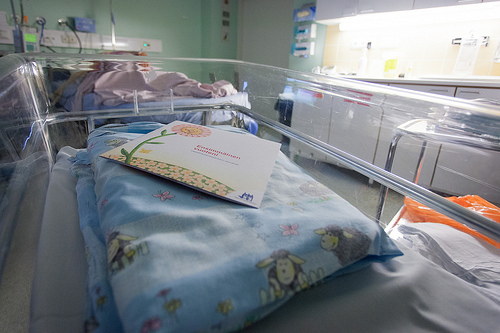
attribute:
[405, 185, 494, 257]
bag — orange, plastic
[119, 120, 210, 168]
flower — pink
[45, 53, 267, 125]
person — lying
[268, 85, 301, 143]
trash bin — black 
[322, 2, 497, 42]
lighting — flourescent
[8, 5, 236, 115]
wall — light green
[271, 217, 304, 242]
butterfly — pink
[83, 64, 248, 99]
blanket — pink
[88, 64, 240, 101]
blanket — pink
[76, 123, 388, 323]
blanket — blue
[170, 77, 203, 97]
glove — exam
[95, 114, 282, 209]
card — white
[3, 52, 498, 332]
bassinet — clear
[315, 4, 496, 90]
lights — bright, white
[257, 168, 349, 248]
blanket — blue, baby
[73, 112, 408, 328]
blanket — blue, baby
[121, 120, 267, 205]
envelope — white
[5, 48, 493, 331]
baby incubator — plastic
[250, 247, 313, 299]
sheep — brown, cartoon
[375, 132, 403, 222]
leg — metal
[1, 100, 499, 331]
baby bed — plastic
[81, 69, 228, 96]
blanket — pink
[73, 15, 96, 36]
equipment — purple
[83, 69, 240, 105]
blanket — pink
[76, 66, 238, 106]
sheet — pink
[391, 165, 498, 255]
bag — orange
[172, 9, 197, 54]
wall — green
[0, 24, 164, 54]
outlet strip — electrical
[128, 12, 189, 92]
light — green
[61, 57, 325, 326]
bed — hospital bed